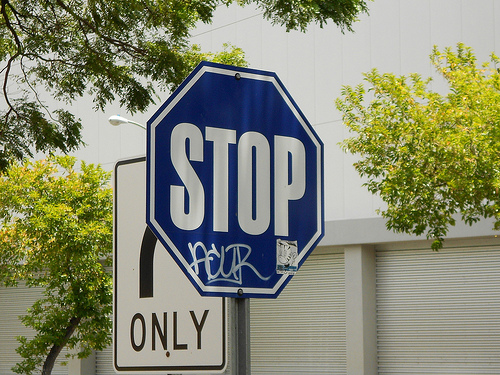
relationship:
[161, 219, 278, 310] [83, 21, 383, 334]
graffiti on a sign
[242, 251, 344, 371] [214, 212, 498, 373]
door in a building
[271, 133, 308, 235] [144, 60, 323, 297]
letter on a sign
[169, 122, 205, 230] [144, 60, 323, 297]
letter on a sign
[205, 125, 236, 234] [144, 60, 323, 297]
letter on a sign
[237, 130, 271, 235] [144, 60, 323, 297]
letter on a sign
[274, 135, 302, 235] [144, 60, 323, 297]
letter on a sign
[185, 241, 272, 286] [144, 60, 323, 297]
letter on a sign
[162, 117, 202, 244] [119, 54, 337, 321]
letter on a sign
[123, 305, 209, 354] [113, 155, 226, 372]
word on a sign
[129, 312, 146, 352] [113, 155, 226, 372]
letter on a sign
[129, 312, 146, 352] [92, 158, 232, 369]
letter on a sign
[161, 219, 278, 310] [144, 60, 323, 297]
graffiti on sign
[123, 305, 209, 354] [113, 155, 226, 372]
word on sign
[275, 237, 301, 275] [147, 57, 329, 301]
square sticker on stop sign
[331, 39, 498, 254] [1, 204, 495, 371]
leaves partly covering other building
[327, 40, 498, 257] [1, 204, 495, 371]
tree near building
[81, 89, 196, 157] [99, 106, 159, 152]
street lamp has top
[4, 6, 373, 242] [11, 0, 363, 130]
tree has branches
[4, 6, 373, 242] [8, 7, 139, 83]
tree has leaves